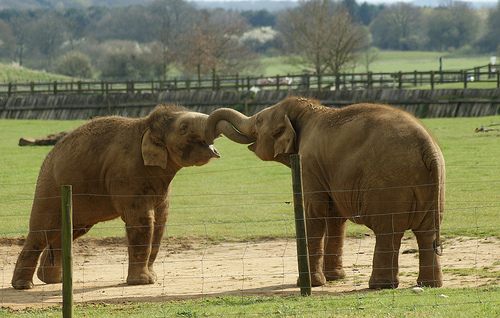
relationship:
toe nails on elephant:
[13, 271, 436, 291] [198, 92, 451, 295]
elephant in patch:
[198, 92, 451, 295] [1, 235, 498, 300]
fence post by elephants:
[287, 153, 313, 298] [13, 87, 452, 298]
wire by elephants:
[3, 180, 58, 315] [13, 87, 452, 298]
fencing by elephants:
[0, 145, 498, 316] [13, 87, 452, 298]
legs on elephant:
[6, 196, 168, 290] [6, 99, 243, 294]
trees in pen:
[52, 1, 374, 82] [0, 62, 500, 241]